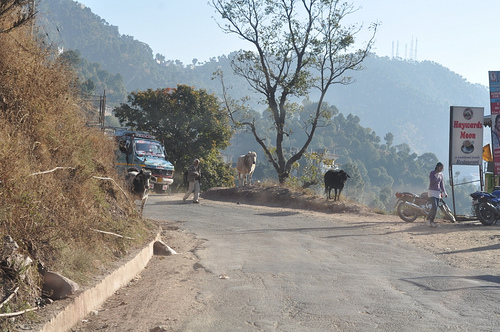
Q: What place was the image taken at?
A: It was taken at the road.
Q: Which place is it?
A: It is a road.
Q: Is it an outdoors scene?
A: Yes, it is outdoors.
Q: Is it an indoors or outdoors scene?
A: It is outdoors.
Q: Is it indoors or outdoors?
A: It is outdoors.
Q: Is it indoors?
A: No, it is outdoors.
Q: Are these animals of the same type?
A: Yes, all the animals are cows.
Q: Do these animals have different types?
A: No, all the animals are cows.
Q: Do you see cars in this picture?
A: No, there are no cars.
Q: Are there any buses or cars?
A: No, there are no cars or buses.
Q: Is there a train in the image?
A: No, there are no trains.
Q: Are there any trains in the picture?
A: No, there are no trains.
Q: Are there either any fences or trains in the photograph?
A: No, there are no trains or fences.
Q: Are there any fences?
A: No, there are no fences.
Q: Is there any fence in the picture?
A: No, there are no fences.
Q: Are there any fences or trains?
A: No, there are no fences or trains.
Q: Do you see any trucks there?
A: Yes, there is a truck.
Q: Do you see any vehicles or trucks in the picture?
A: Yes, there is a truck.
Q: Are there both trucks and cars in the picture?
A: No, there is a truck but no cars.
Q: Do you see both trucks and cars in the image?
A: No, there is a truck but no cars.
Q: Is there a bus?
A: No, there are no buses.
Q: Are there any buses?
A: No, there are no buses.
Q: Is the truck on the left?
A: Yes, the truck is on the left of the image.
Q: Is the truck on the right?
A: No, the truck is on the left of the image.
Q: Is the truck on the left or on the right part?
A: The truck is on the left of the image.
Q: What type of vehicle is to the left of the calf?
A: The vehicle is a truck.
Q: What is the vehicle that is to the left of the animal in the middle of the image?
A: The vehicle is a truck.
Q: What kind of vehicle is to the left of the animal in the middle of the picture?
A: The vehicle is a truck.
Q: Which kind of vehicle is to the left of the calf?
A: The vehicle is a truck.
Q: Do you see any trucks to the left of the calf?
A: Yes, there is a truck to the left of the calf.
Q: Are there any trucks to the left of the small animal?
A: Yes, there is a truck to the left of the calf.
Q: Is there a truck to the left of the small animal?
A: Yes, there is a truck to the left of the calf.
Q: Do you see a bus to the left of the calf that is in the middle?
A: No, there is a truck to the left of the calf.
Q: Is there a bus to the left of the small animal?
A: No, there is a truck to the left of the calf.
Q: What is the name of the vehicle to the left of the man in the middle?
A: The vehicle is a truck.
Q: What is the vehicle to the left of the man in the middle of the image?
A: The vehicle is a truck.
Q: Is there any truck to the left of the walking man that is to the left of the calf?
A: Yes, there is a truck to the left of the man.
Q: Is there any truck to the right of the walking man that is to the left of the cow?
A: No, the truck is to the left of the man.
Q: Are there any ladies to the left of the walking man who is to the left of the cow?
A: No, there is a truck to the left of the man.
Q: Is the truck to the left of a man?
A: Yes, the truck is to the left of a man.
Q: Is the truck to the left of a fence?
A: No, the truck is to the left of a man.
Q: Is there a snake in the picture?
A: No, there are no snakes.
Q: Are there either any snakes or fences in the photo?
A: No, there are no snakes or fences.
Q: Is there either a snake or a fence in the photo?
A: No, there are no snakes or fences.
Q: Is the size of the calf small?
A: Yes, the calf is small.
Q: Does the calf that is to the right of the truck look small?
A: Yes, the calf is small.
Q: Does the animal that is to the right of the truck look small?
A: Yes, the calf is small.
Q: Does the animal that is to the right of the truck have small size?
A: Yes, the calf is small.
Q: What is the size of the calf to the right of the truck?
A: The calf is small.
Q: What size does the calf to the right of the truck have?
A: The calf has small size.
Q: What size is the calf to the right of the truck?
A: The calf is small.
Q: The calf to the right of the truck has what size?
A: The calf is small.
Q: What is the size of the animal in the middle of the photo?
A: The calf is small.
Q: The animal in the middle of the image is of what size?
A: The calf is small.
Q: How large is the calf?
A: The calf is small.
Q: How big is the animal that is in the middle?
A: The calf is small.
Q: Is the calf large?
A: No, the calf is small.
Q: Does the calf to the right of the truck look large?
A: No, the calf is small.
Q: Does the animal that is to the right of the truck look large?
A: No, the calf is small.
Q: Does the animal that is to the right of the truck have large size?
A: No, the calf is small.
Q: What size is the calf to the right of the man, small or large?
A: The calf is small.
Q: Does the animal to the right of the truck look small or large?
A: The calf is small.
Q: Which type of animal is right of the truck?
A: The animal is a calf.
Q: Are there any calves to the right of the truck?
A: Yes, there is a calf to the right of the truck.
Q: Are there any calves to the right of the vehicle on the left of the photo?
A: Yes, there is a calf to the right of the truck.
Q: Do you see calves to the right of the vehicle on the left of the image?
A: Yes, there is a calf to the right of the truck.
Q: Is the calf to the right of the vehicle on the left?
A: Yes, the calf is to the right of the truck.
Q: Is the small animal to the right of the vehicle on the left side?
A: Yes, the calf is to the right of the truck.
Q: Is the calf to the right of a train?
A: No, the calf is to the right of the truck.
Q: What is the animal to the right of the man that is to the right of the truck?
A: The animal is a calf.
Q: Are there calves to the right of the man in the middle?
A: Yes, there is a calf to the right of the man.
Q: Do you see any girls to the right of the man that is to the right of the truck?
A: No, there is a calf to the right of the man.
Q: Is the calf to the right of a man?
A: Yes, the calf is to the right of a man.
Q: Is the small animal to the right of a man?
A: Yes, the calf is to the right of a man.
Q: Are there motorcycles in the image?
A: Yes, there is a motorcycle.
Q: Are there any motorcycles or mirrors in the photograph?
A: Yes, there is a motorcycle.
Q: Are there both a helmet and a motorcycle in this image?
A: No, there is a motorcycle but no helmets.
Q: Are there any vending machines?
A: No, there are no vending machines.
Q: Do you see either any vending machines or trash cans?
A: No, there are no vending machines or trash cans.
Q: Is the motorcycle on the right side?
A: Yes, the motorcycle is on the right of the image.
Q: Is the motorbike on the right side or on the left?
A: The motorbike is on the right of the image.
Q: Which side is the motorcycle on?
A: The motorcycle is on the right of the image.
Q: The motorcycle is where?
A: The motorcycle is on the road.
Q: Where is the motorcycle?
A: The motorcycle is on the road.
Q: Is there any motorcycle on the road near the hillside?
A: Yes, there is a motorcycle on the road.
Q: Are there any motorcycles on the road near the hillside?
A: Yes, there is a motorcycle on the road.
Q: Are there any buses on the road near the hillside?
A: No, there is a motorcycle on the road.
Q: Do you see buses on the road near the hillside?
A: No, there is a motorcycle on the road.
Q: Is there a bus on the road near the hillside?
A: No, there is a motorcycle on the road.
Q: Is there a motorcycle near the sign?
A: Yes, there is a motorcycle near the sign.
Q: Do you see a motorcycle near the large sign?
A: Yes, there is a motorcycle near the sign.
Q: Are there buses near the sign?
A: No, there is a motorcycle near the sign.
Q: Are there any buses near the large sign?
A: No, there is a motorcycle near the sign.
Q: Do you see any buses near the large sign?
A: No, there is a motorcycle near the sign.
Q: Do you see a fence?
A: No, there are no fences.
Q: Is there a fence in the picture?
A: No, there are no fences.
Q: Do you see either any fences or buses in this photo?
A: No, there are no fences or buses.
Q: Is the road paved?
A: Yes, the road is paved.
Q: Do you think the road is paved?
A: Yes, the road is paved.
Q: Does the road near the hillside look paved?
A: Yes, the road is paved.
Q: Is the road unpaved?
A: No, the road is paved.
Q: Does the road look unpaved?
A: No, the road is paved.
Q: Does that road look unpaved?
A: No, the road is paved.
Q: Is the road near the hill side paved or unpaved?
A: The road is paved.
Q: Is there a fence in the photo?
A: No, there are no fences.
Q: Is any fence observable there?
A: No, there are no fences.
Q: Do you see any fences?
A: No, there are no fences.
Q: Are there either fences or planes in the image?
A: No, there are no fences or planes.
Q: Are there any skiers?
A: No, there are no skiers.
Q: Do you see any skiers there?
A: No, there are no skiers.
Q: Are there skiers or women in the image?
A: No, there are no skiers or women.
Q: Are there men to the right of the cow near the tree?
A: Yes, there is a man to the right of the cow.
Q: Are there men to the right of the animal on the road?
A: Yes, there is a man to the right of the cow.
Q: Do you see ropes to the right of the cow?
A: No, there is a man to the right of the cow.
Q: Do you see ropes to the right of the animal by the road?
A: No, there is a man to the right of the cow.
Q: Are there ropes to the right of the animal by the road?
A: No, there is a man to the right of the cow.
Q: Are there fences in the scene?
A: No, there are no fences.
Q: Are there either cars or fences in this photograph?
A: No, there are no fences or cars.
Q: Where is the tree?
A: The tree is on the hill.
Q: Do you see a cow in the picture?
A: Yes, there is a cow.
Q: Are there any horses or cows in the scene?
A: Yes, there is a cow.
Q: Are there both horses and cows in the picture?
A: No, there is a cow but no horses.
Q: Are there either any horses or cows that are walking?
A: Yes, the cow is walking.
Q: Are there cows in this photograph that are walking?
A: Yes, there is a cow that is walking.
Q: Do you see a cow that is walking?
A: Yes, there is a cow that is walking.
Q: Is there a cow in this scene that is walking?
A: Yes, there is a cow that is walking.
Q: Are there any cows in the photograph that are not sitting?
A: Yes, there is a cow that is walking.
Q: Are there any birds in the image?
A: No, there are no birds.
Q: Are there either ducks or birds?
A: No, there are no birds or ducks.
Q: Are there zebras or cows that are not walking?
A: No, there is a cow but it is walking.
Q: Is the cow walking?
A: Yes, the cow is walking.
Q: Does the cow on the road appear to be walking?
A: Yes, the cow is walking.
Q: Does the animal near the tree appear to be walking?
A: Yes, the cow is walking.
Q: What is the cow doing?
A: The cow is walking.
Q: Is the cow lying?
A: No, the cow is walking.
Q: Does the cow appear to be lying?
A: No, the cow is walking.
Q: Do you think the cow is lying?
A: No, the cow is walking.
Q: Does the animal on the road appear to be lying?
A: No, the cow is walking.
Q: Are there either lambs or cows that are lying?
A: No, there is a cow but it is walking.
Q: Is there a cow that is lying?
A: No, there is a cow but it is walking.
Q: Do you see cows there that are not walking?
A: No, there is a cow but it is walking.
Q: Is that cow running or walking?
A: The cow is walking.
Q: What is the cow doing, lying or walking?
A: The cow is walking.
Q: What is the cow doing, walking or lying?
A: The cow is walking.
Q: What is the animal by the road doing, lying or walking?
A: The cow is walking.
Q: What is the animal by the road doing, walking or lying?
A: The cow is walking.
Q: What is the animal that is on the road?
A: The animal is a cow.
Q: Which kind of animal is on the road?
A: The animal is a cow.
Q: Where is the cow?
A: The cow is on the road.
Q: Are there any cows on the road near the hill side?
A: Yes, there is a cow on the road.